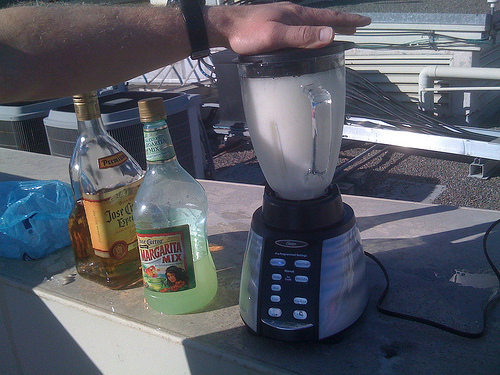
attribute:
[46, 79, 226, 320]
bottles — couple, alcohol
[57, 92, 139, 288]
beverage — alcoholic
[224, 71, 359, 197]
beverages — adult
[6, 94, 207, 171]
units — air conditioner, couple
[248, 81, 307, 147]
liquid — white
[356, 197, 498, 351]
wire — black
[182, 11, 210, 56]
band — black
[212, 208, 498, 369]
surface — gray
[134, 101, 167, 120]
cap — gold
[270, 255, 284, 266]
button — white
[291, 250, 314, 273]
button — white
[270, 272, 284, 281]
button — white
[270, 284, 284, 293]
button — white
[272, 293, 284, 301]
button — white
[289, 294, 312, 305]
button — white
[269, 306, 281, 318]
button — white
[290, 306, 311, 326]
button — white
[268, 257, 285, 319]
buttons — white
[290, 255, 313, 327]
buttons — white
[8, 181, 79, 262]
bag — blue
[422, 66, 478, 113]
pipe — white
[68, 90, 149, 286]
bottle — big